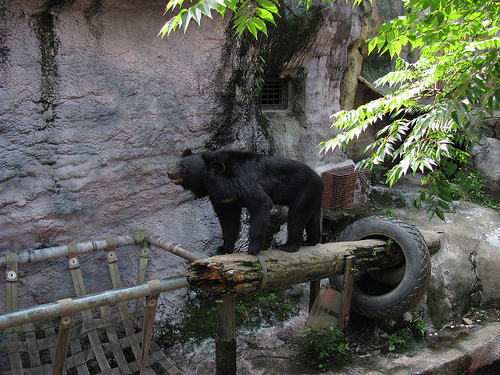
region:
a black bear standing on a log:
[160, 143, 330, 268]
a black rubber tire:
[338, 212, 433, 310]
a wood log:
[177, 225, 451, 302]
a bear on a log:
[165, 126, 335, 280]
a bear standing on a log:
[163, 129, 325, 276]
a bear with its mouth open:
[164, 149, 201, 188]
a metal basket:
[323, 162, 371, 214]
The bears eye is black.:
[179, 164, 189, 171]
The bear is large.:
[168, 149, 335, 248]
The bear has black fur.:
[170, 144, 326, 252]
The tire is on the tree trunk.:
[333, 212, 438, 321]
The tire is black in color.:
[338, 212, 433, 323]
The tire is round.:
[329, 212, 435, 326]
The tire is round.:
[333, 218, 429, 321]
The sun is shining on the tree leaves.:
[323, 94, 473, 193]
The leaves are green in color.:
[318, 93, 466, 173]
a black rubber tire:
[400, 252, 436, 316]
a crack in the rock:
[460, 234, 491, 295]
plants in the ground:
[246, 297, 297, 338]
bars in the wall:
[267, 81, 291, 113]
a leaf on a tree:
[389, 66, 452, 169]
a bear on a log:
[225, 148, 332, 280]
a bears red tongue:
[159, 153, 204, 196]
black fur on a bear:
[236, 149, 278, 192]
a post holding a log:
[206, 305, 249, 356]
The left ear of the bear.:
[180, 148, 194, 155]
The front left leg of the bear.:
[215, 200, 240, 251]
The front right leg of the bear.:
[245, 194, 274, 256]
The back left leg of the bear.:
[304, 205, 319, 244]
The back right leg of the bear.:
[285, 184, 302, 254]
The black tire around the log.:
[332, 219, 427, 321]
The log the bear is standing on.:
[180, 224, 440, 302]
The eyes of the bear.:
[175, 162, 187, 170]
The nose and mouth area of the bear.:
[166, 169, 180, 184]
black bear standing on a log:
[158, 135, 329, 254]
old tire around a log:
[329, 213, 435, 317]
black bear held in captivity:
[164, 140, 326, 255]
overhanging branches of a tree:
[158, 0, 499, 212]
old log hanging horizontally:
[184, 226, 444, 293]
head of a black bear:
[163, 149, 211, 192]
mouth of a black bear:
[163, 173, 190, 191]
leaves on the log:
[243, 256, 269, 282]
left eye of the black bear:
[179, 163, 191, 174]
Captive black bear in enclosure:
[166, 146, 327, 256]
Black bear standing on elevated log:
[167, 146, 327, 255]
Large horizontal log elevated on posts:
[185, 230, 444, 372]